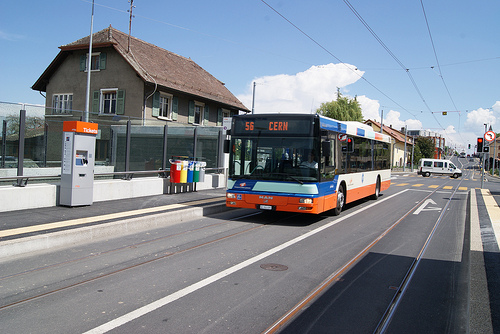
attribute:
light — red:
[476, 137, 486, 153]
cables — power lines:
[267, 4, 499, 124]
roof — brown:
[65, 7, 255, 108]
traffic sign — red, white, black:
[467, 115, 499, 151]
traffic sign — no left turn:
[482, 129, 496, 144]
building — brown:
[30, 23, 252, 165]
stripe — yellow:
[455, 183, 467, 191]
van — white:
[417, 157, 463, 179]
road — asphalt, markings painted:
[60, 158, 492, 315]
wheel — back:
[372, 175, 382, 200]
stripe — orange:
[224, 178, 391, 217]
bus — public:
[227, 112, 392, 216]